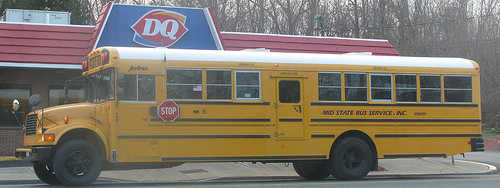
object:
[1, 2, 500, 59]
trees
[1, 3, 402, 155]
building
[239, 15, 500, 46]
wire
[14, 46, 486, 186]
bus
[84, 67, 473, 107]
windows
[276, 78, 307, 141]
door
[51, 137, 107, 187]
tire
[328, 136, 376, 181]
tire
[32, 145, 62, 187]
tire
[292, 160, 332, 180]
tire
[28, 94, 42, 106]
mirror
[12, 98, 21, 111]
mirror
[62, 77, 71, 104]
mirror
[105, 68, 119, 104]
mirror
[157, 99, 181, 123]
stop sign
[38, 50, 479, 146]
lights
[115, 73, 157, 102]
driver's window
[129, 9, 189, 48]
dairy queen logo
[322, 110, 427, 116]
black print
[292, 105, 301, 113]
handle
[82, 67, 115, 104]
windshield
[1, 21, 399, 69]
roof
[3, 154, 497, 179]
sidewalk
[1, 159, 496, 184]
yellow line